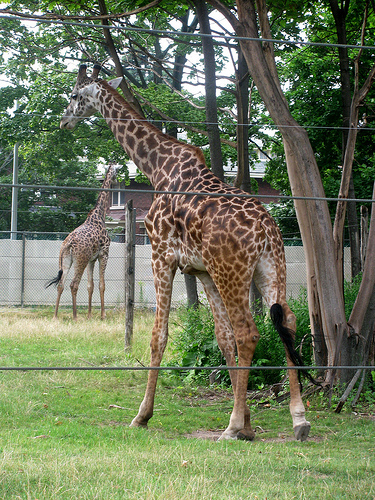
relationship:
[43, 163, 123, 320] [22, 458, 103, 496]
animal standing on grass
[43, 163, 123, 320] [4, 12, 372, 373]
animal standing inside enclosure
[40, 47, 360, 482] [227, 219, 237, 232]
animal has spot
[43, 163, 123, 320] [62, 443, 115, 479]
animal standing on grass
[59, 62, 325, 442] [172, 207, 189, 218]
animal has spot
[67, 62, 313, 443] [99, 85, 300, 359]
animal has spots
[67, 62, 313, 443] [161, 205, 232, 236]
animal has dark spots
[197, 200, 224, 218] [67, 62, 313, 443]
spots on top of animal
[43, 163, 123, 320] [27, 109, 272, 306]
animal inside of enclosure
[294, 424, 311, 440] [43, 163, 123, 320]
giraffe hoof on back of animal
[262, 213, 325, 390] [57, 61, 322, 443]
tail on back of giraffe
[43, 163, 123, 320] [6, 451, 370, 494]
animal standing on grass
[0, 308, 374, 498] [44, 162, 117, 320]
grass by giraffe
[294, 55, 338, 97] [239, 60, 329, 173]
leaves in tree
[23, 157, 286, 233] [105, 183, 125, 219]
house has window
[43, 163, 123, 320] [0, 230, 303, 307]
animal behind a fence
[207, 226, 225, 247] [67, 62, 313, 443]
dark spot front of animal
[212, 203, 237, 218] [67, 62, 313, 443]
dark spot front of animal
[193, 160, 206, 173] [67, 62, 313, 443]
dark spot front of animal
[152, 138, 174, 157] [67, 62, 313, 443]
dark spot front of animal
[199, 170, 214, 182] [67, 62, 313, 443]
dark spot front of animal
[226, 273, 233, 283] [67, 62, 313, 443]
spot on animal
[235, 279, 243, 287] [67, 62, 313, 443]
spot on animal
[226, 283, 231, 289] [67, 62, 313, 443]
spot on animal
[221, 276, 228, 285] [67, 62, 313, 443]
spot on animal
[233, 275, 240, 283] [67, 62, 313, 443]
spot on animal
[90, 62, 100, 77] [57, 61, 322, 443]
horn on a giraffe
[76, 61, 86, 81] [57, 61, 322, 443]
horn on a giraffe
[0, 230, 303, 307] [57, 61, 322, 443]
fence behind giraffe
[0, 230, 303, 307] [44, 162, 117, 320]
fence behind giraffe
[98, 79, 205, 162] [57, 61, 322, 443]
mane on a giraffe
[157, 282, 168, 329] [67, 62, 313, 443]
spots on animal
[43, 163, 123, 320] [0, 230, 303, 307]
animal in a fence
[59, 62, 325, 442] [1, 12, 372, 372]
animal fenced in a pen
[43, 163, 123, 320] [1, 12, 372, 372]
animal fenced in a pen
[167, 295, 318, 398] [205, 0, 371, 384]
bush behind a tree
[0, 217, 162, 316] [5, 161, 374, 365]
fence in a pen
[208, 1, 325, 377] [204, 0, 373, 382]
edge of a stem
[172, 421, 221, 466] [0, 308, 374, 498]
part of a grass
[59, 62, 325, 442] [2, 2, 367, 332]
animal near trees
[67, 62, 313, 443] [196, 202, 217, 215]
animal has spots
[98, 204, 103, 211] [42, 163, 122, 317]
spots has animal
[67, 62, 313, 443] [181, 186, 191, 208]
animal has dark spots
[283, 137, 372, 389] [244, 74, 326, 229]
trunk of a tree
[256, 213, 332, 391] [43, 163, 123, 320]
tail of animal